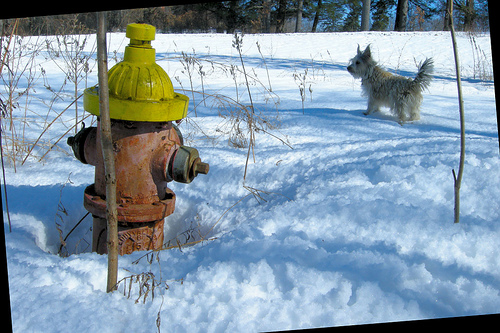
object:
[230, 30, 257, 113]
shrubbage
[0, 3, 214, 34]
trees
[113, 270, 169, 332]
leaves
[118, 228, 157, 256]
symbol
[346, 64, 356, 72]
nose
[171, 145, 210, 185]
knob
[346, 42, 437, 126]
dog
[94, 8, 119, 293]
tree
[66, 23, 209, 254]
fire hydrant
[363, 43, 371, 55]
ear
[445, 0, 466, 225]
baseball player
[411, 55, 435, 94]
tail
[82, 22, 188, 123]
top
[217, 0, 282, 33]
trees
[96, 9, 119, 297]
skinny trunk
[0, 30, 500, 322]
ground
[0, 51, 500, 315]
shadows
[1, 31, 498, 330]
snow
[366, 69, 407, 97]
fur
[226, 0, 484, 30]
sky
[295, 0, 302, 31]
tree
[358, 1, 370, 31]
tree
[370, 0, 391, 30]
tree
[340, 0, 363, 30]
tree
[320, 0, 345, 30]
tree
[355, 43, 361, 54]
ear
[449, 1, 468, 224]
tree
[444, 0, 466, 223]
trunk